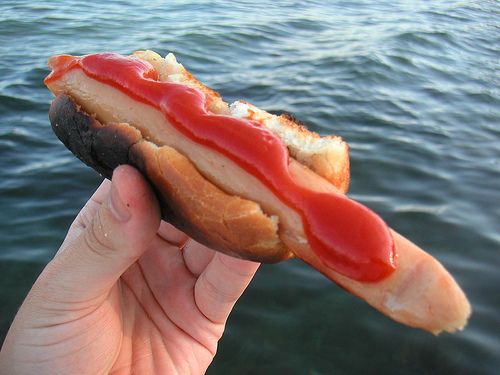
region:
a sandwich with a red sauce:
[51, 33, 462, 345]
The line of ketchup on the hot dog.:
[77, 51, 399, 273]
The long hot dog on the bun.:
[48, 52, 472, 347]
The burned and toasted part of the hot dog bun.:
[44, 101, 201, 230]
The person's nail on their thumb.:
[99, 170, 131, 226]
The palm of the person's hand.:
[9, 231, 209, 373]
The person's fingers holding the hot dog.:
[89, 194, 256, 317]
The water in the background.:
[4, 5, 497, 346]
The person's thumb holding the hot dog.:
[69, 163, 164, 274]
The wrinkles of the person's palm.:
[54, 224, 207, 374]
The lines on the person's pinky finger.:
[208, 251, 248, 313]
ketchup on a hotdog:
[48, 55, 398, 281]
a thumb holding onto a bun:
[42, 165, 167, 291]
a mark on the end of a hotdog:
[381, 252, 442, 304]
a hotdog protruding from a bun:
[50, 50, 471, 327]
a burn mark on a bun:
[41, 91, 156, 203]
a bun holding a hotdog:
[45, 42, 350, 253]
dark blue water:
[0, 0, 495, 367]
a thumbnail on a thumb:
[101, 177, 136, 222]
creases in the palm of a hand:
[113, 255, 221, 358]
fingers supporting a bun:
[97, 178, 263, 327]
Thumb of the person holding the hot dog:
[57, 161, 147, 288]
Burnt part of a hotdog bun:
[51, 93, 121, 173]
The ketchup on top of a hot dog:
[302, 182, 394, 279]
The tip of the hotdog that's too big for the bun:
[406, 238, 476, 345]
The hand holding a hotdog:
[12, 161, 244, 371]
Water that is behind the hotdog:
[354, 75, 494, 195]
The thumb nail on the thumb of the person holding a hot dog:
[105, 182, 133, 222]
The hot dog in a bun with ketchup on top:
[36, 41, 472, 339]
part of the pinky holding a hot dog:
[206, 248, 240, 326]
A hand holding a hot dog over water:
[8, 26, 473, 358]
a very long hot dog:
[43, 48, 468, 339]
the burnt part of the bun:
[45, 90, 145, 212]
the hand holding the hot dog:
[9, 166, 246, 370]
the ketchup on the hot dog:
[44, 41, 387, 302]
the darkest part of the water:
[229, 279, 438, 372]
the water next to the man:
[3, 4, 493, 369]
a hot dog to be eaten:
[42, 40, 471, 340]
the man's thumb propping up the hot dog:
[50, 159, 159, 303]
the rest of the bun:
[138, 47, 357, 179]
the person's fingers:
[157, 221, 247, 321]